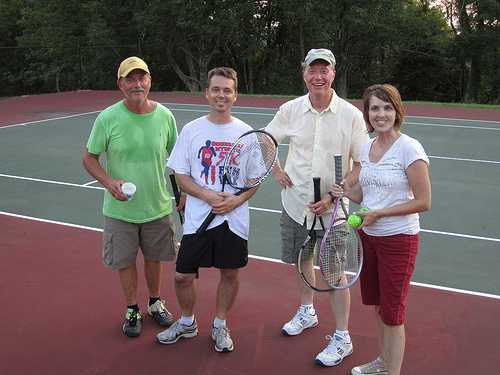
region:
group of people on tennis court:
[98, 32, 418, 351]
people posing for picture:
[70, 18, 432, 329]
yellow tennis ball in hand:
[344, 208, 363, 233]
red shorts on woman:
[354, 223, 421, 323]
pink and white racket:
[310, 210, 365, 295]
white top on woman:
[344, 129, 427, 242]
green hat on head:
[300, 51, 331, 66]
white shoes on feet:
[285, 303, 358, 369]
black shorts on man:
[178, 223, 255, 275]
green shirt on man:
[92, 100, 187, 224]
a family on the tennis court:
[3, 23, 498, 371]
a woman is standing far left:
[346, 79, 429, 372]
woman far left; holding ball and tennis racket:
[320, 157, 364, 291]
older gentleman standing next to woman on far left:
[262, 43, 359, 365]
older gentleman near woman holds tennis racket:
[293, 171, 345, 297]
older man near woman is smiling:
[306, 82, 331, 88]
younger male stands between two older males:
[160, 70, 255, 350]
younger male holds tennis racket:
[216, 128, 276, 200]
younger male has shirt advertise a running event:
[196, 133, 244, 190]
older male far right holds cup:
[110, 180, 137, 201]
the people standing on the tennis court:
[80, 45, 430, 372]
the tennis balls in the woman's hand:
[347, 207, 371, 227]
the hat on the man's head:
[305, 48, 335, 66]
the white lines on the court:
[0, 103, 499, 300]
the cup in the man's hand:
[118, 181, 135, 199]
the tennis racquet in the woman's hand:
[320, 153, 363, 289]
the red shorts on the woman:
[355, 224, 418, 325]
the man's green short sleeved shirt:
[85, 100, 177, 222]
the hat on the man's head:
[116, 55, 148, 76]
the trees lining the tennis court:
[0, 1, 498, 103]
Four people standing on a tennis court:
[2, 44, 497, 373]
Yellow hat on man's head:
[113, 50, 157, 108]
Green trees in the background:
[2, 1, 499, 101]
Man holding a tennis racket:
[168, 62, 282, 232]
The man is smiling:
[297, 45, 339, 101]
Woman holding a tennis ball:
[345, 80, 437, 236]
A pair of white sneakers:
[276, 302, 355, 370]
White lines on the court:
[0, 98, 499, 307]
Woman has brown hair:
[359, 81, 406, 138]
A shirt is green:
[84, 95, 181, 226]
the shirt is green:
[85, 101, 173, 222]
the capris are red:
[355, 223, 420, 323]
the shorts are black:
[175, 227, 250, 271]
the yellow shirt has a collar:
[263, 91, 370, 223]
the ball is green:
[344, 210, 363, 231]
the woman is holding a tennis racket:
[319, 82, 429, 373]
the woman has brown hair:
[360, 80, 406, 134]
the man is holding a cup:
[116, 179, 136, 201]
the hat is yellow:
[112, 52, 152, 82]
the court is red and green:
[0, 84, 498, 374]